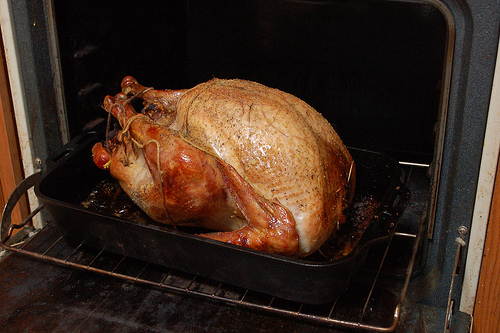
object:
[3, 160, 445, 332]
rack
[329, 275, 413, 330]
gauge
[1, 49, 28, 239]
door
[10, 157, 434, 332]
metal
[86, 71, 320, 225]
nicely browned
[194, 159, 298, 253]
chicken wing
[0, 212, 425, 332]
grill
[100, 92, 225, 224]
legs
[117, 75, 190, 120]
legs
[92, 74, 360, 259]
turkey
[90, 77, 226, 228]
drumstick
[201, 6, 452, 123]
wall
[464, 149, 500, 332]
wood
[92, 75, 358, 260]
chicken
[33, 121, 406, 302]
pan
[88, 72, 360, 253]
poultry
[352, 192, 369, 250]
drippings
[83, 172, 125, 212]
drippings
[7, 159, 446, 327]
mesh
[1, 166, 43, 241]
hinge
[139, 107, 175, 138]
string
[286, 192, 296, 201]
dot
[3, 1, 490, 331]
oven door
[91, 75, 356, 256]
cooked food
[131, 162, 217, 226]
thigh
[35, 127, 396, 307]
roasting pan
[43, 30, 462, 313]
oven